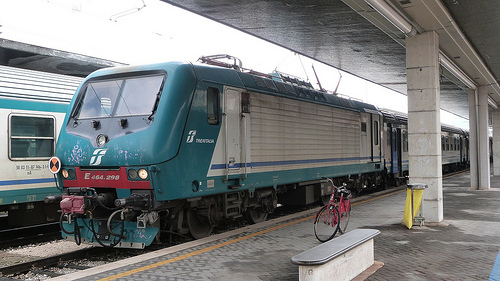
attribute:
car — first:
[46, 49, 384, 255]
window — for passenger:
[11, 116, 54, 159]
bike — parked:
[298, 172, 426, 274]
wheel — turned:
[305, 205, 350, 245]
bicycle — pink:
[314, 176, 352, 239]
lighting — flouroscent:
[379, 29, 449, 73]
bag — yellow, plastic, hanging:
[380, 183, 448, 234]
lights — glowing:
[37, 167, 163, 193]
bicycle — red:
[317, 177, 354, 242]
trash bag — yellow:
[403, 183, 424, 227]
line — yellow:
[129, 240, 192, 266]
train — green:
[51, 61, 379, 264]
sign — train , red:
[68, 159, 148, 200]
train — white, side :
[49, 56, 452, 262]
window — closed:
[83, 78, 163, 123]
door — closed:
[367, 114, 406, 174]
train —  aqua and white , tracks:
[56, 55, 466, 242]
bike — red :
[305, 175, 354, 250]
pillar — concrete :
[406, 30, 445, 223]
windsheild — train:
[67, 77, 165, 129]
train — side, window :
[72, 80, 172, 127]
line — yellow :
[150, 236, 221, 270]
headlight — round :
[44, 152, 64, 172]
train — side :
[43, 61, 477, 247]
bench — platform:
[275, 225, 398, 278]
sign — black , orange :
[41, 150, 71, 169]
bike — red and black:
[309, 181, 357, 241]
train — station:
[22, 19, 480, 272]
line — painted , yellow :
[144, 238, 243, 270]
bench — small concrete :
[284, 220, 393, 278]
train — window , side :
[203, 87, 217, 111]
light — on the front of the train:
[129, 165, 150, 180]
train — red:
[39, 28, 401, 238]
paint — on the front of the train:
[75, 171, 127, 182]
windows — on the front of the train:
[79, 71, 168, 114]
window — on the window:
[77, 64, 166, 124]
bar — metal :
[110, 76, 126, 122]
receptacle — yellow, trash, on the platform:
[403, 183, 423, 240]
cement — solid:
[395, 257, 469, 278]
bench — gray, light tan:
[267, 216, 398, 279]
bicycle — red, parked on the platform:
[307, 175, 368, 239]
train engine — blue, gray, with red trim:
[49, 190, 152, 237]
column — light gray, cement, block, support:
[395, 25, 457, 184]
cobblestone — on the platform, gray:
[187, 260, 217, 276]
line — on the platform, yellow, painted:
[159, 251, 210, 261]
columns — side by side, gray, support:
[406, 37, 444, 176]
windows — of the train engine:
[74, 66, 167, 129]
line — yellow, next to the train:
[124, 252, 206, 270]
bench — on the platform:
[294, 220, 395, 279]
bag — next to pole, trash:
[402, 190, 411, 225]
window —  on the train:
[6, 108, 57, 158]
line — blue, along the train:
[213, 154, 380, 172]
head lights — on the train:
[49, 160, 164, 189]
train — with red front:
[38, 59, 398, 216]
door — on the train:
[366, 103, 387, 163]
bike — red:
[317, 176, 360, 232]